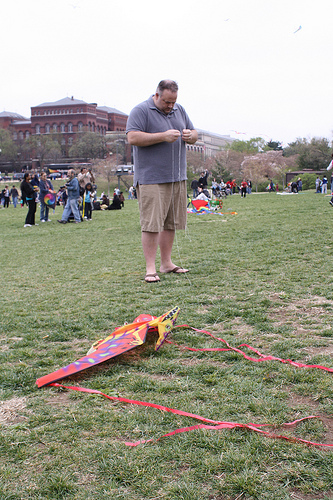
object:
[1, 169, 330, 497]
park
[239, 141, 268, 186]
tree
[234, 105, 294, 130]
blue sky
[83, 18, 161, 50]
white clouds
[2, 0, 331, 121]
sky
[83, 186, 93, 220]
child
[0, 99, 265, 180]
buildings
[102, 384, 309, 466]
tail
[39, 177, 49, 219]
woman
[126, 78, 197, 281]
man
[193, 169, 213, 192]
man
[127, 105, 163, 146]
arm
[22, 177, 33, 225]
people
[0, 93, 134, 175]
building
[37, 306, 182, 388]
kite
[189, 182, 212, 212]
person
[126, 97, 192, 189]
shirt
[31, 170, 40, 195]
child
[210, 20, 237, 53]
clouds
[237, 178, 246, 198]
person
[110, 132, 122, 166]
trees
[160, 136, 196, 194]
ribbons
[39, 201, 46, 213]
jeans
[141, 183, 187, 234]
shorts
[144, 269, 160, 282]
feet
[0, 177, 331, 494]
grass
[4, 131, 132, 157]
row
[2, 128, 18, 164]
tree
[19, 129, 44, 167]
tree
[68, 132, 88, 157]
tree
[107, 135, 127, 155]
tree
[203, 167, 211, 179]
object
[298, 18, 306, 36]
kite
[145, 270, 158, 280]
flip flops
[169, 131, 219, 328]
string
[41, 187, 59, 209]
kite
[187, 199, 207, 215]
kites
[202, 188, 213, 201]
chair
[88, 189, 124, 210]
people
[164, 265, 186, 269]
flip flops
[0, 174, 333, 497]
field